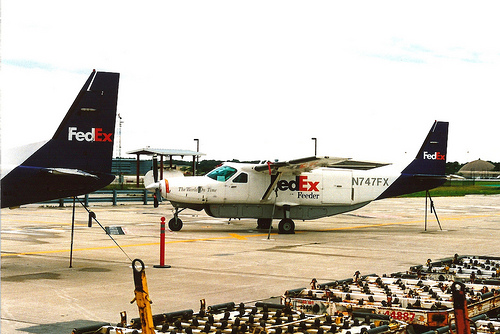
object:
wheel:
[275, 217, 294, 234]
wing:
[250, 155, 352, 178]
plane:
[140, 119, 449, 235]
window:
[230, 171, 250, 184]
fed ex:
[420, 149, 444, 161]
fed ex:
[66, 125, 114, 144]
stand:
[152, 215, 172, 269]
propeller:
[147, 151, 163, 208]